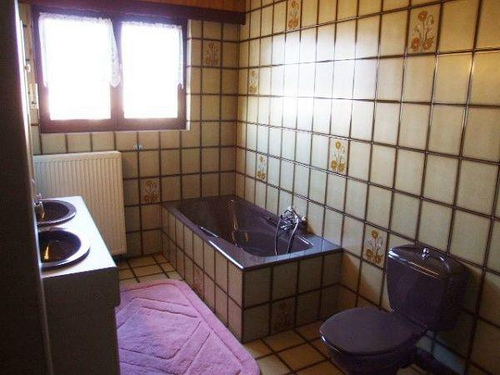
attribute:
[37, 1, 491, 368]
tiles — brown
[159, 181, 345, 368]
tub — ceramic, bath, tiled, dark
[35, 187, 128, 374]
sinks — double, dual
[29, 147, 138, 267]
heater — white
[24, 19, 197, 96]
curtains — lace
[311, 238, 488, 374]
toilet — grey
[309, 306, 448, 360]
lid — closed, down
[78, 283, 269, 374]
bathmat — pink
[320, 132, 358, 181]
tiles — accent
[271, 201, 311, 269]
fixtures — chrome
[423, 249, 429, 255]
button — chrome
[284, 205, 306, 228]
knobs — silver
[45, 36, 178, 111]
light — shining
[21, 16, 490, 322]
walls — tile, brown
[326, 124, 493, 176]
grout — dark